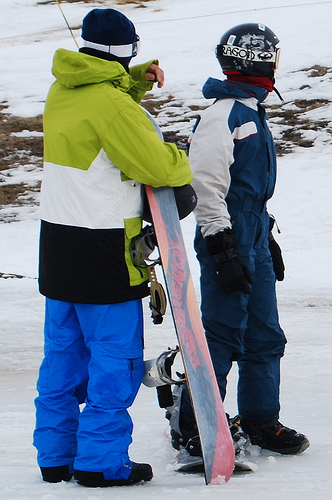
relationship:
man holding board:
[31, 6, 192, 488] [145, 182, 236, 488]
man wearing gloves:
[170, 20, 309, 456] [205, 230, 252, 296]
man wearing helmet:
[170, 20, 309, 456] [210, 11, 296, 95]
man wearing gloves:
[165, 20, 309, 454] [200, 227, 254, 295]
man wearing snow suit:
[170, 20, 309, 456] [164, 74, 293, 443]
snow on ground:
[2, 2, 331, 499] [1, 0, 330, 498]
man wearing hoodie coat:
[31, 6, 195, 485] [35, 47, 193, 301]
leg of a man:
[239, 248, 286, 437] [165, 20, 309, 454]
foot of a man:
[238, 416, 309, 456] [165, 20, 309, 454]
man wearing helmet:
[170, 20, 309, 456] [212, 21, 282, 78]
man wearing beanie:
[31, 6, 195, 485] [77, 9, 141, 69]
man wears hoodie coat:
[31, 6, 195, 485] [35, 47, 193, 307]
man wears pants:
[31, 6, 192, 488] [32, 295, 143, 479]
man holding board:
[31, 6, 192, 488] [139, 107, 237, 486]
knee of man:
[256, 323, 286, 359] [184, 22, 309, 458]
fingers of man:
[143, 63, 167, 92] [31, 6, 195, 485]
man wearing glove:
[165, 20, 309, 454] [203, 225, 254, 294]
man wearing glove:
[165, 20, 309, 454] [268, 215, 285, 280]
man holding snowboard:
[31, 6, 192, 488] [141, 104, 235, 484]